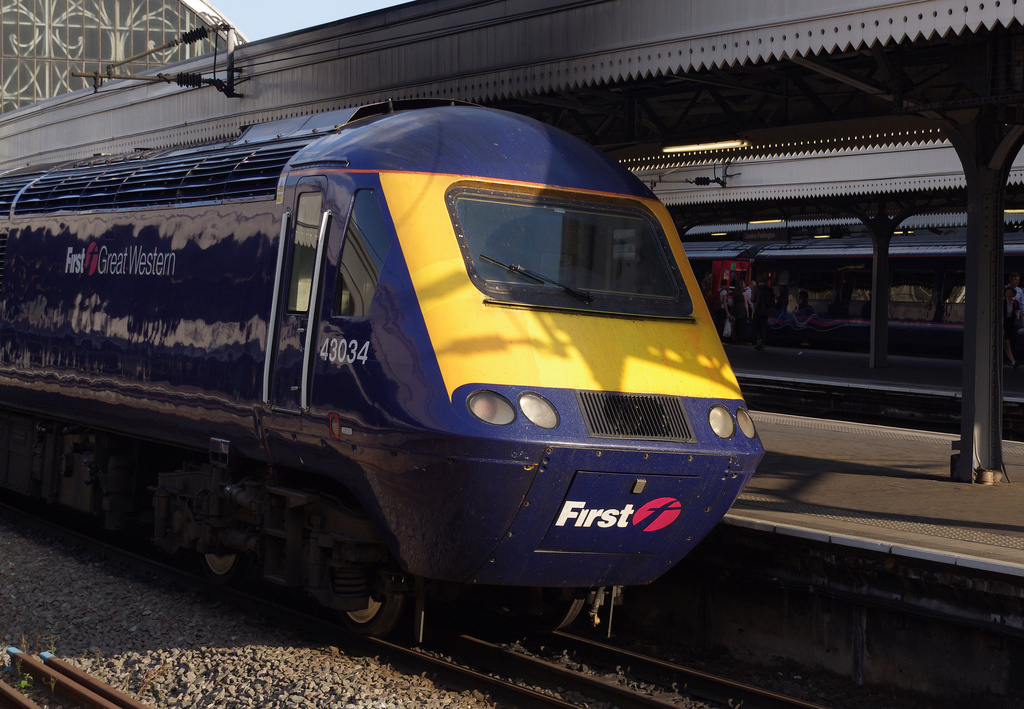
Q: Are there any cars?
A: No, there are no cars.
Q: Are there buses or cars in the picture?
A: No, there are no cars or buses.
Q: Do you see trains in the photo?
A: Yes, there is a train.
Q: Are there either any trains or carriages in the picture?
A: Yes, there is a train.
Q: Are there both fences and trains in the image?
A: No, there is a train but no fences.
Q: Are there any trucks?
A: No, there are no trucks.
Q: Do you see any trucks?
A: No, there are no trucks.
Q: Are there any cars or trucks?
A: No, there are no trucks or cars.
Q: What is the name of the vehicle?
A: The vehicle is a train.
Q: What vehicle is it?
A: The vehicle is a train.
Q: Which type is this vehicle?
A: This is a train.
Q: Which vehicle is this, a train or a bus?
A: This is a train.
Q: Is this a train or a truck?
A: This is a train.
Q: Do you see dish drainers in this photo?
A: No, there are no dish drainers.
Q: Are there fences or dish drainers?
A: No, there are no dish drainers or fences.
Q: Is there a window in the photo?
A: Yes, there is a window.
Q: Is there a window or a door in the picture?
A: Yes, there is a window.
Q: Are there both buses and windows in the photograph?
A: No, there is a window but no buses.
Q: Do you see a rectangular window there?
A: Yes, there is a rectangular window.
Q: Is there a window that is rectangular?
A: Yes, there is a window that is rectangular.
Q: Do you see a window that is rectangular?
A: Yes, there is a window that is rectangular.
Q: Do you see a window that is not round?
A: Yes, there is a rectangular window.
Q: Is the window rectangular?
A: Yes, the window is rectangular.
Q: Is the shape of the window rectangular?
A: Yes, the window is rectangular.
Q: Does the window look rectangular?
A: Yes, the window is rectangular.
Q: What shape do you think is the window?
A: The window is rectangular.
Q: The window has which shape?
A: The window is rectangular.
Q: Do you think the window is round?
A: No, the window is rectangular.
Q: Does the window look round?
A: No, the window is rectangular.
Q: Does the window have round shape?
A: No, the window is rectangular.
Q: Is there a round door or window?
A: No, there is a window but it is rectangular.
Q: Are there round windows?
A: No, there is a window but it is rectangular.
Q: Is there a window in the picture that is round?
A: No, there is a window but it is rectangular.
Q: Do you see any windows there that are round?
A: No, there is a window but it is rectangular.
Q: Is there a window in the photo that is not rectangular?
A: No, there is a window but it is rectangular.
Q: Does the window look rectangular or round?
A: The window is rectangular.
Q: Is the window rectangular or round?
A: The window is rectangular.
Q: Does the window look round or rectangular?
A: The window is rectangular.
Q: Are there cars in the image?
A: No, there are no cars.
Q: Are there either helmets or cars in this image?
A: No, there are no cars or helmets.